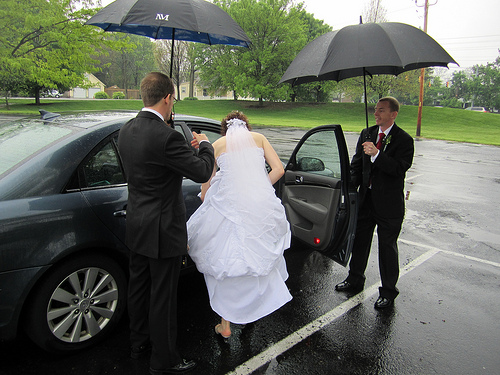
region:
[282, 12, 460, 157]
An all black umbrella a man is holding while he holds a door too.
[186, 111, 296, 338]
A bride in a white dress entering a car.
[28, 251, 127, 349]
Back black and silver wheel of a car.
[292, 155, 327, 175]
Passenger side rear view mirror.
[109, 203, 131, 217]
Back passenger side door handle.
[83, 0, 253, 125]
Black umbrella with white and blue sky on the inside.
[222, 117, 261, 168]
White veil coming off the back of a brides hair.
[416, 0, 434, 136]
Brown electric pole behind a black umbrella.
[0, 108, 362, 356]
Blue car a bride is getting into.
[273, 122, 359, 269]
Passenger side door that is being held open.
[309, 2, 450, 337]
man holding a black umbella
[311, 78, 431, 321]
man wearing a black suit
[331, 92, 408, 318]
man wearing a red tie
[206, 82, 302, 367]
woman weraing a white dress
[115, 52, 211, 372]
man wearing a black suit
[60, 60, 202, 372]
man wearing a white shirt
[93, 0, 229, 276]
man holdng an umbrella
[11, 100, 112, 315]
gray car parked in lot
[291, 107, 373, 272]
door on a car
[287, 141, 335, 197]
mirror on a door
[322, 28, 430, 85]
black plain wet umbrella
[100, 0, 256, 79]
blck umbrella with letter NM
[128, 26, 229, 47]
printed clouds underneath umbrella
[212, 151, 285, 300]
white riffled wedding dress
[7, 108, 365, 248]
blue colored sedan car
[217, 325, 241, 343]
silver and clear wedding shoes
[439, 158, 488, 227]
wet asphalt parking lot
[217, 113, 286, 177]
white clear wedding veil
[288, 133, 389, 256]
inside of car door open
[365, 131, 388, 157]
red ties on groomsmen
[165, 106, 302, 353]
A woman in a white wedding dress.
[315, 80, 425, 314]
A man wearing a black suit.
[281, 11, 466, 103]
a black umbrella.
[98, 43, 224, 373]
A groom in a black tux.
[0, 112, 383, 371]
A parked black car.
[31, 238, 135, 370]
a rear white wheel.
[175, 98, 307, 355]
a woman in a white dress.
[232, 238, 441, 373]
a white line in a parking lot.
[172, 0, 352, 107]
a lush green leafy tree.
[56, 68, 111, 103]
a house on the side of a road.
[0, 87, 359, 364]
a bride getting into her car on a rainy day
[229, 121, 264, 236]
a bride's veil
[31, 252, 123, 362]
the wheel of a car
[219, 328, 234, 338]
a woman's heel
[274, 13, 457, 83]
the top of an umbrella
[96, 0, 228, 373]
a man in a suit holding an umbrella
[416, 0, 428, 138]
a wooden telephone pole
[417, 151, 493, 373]
a slick wet parking lot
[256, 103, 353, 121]
a large grassy area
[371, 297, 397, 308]
a man's shoe